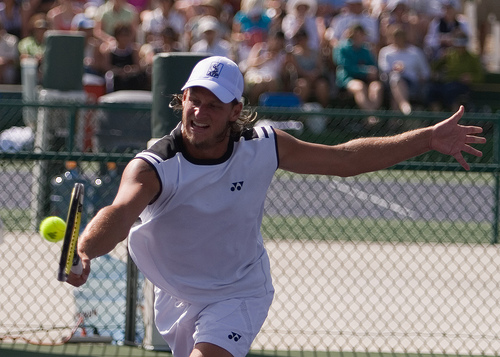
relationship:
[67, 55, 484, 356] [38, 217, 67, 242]
man hitting ball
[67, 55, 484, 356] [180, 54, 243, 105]
man wearing cap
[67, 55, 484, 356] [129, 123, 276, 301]
man wearing shirt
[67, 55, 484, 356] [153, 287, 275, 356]
man wearing shorts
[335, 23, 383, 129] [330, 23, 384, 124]
person sitting in person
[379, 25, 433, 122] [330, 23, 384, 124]
person sitting in person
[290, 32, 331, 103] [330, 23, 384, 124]
person sitting in person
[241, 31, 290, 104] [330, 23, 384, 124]
person sitting in person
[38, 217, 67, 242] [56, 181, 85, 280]
ball bouncing on racket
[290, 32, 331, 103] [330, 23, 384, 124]
person in person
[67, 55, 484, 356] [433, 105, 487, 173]
man has hand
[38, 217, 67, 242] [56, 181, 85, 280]
ball next to racket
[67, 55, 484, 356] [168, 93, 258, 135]
man has hair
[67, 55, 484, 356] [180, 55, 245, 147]
man has head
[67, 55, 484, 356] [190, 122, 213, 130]
man has teeth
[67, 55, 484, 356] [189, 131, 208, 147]
man has chin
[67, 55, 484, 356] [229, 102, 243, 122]
man has ear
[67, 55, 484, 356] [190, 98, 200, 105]
man has eye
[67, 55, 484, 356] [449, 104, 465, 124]
man has thumb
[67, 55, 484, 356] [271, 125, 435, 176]
man has arm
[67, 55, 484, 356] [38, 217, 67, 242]
man returning ball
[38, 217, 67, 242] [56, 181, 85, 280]
ball contacting racket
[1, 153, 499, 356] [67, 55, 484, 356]
fence behind man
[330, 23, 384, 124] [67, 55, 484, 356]
person watching man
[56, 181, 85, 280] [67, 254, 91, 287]
racket in hand